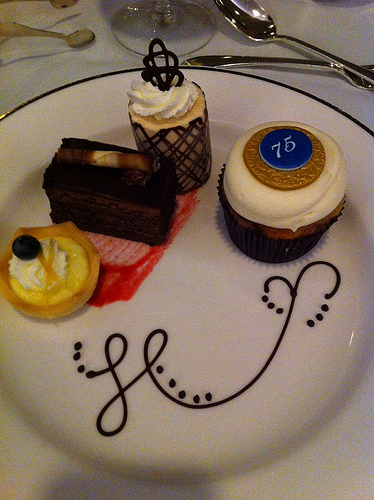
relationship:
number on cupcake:
[272, 134, 296, 159] [218, 121, 350, 266]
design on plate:
[72, 260, 342, 437] [1, 64, 374, 499]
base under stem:
[111, 2, 217, 55] [155, 2, 170, 20]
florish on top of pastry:
[140, 36, 184, 95] [125, 40, 211, 196]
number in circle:
[272, 134, 296, 159] [260, 126, 313, 171]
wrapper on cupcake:
[222, 214, 340, 267] [218, 121, 350, 266]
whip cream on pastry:
[129, 78, 201, 119] [125, 40, 211, 196]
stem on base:
[155, 2, 170, 20] [111, 2, 217, 55]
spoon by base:
[212, 1, 373, 80] [111, 2, 217, 55]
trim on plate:
[1, 73, 120, 120] [1, 64, 374, 499]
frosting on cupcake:
[221, 121, 349, 231] [218, 121, 350, 266]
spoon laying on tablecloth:
[212, 1, 373, 80] [2, 1, 145, 115]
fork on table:
[181, 55, 373, 89] [2, 1, 145, 115]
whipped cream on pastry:
[129, 78, 201, 119] [125, 40, 211, 196]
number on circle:
[272, 134, 296, 159] [260, 126, 313, 171]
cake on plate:
[43, 139, 176, 246] [1, 64, 374, 499]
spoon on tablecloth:
[212, 1, 373, 80] [2, 1, 145, 115]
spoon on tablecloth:
[2, 20, 96, 54] [2, 1, 145, 115]